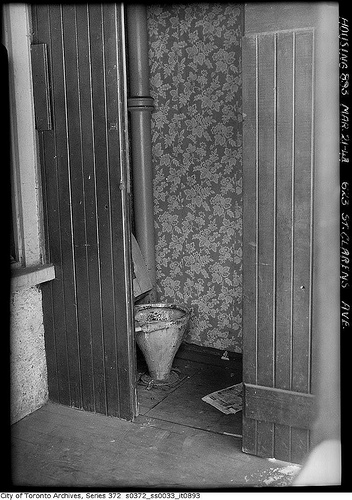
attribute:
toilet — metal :
[132, 303, 198, 388]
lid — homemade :
[133, 237, 154, 301]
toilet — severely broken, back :
[118, 234, 188, 382]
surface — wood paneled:
[245, 28, 323, 421]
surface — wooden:
[60, 414, 187, 482]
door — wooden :
[30, 1, 140, 421]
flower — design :
[179, 103, 217, 141]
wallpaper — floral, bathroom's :
[147, 5, 242, 352]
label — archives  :
[107, 489, 121, 499]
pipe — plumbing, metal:
[127, 34, 157, 254]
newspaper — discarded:
[201, 381, 243, 417]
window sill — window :
[11, 264, 62, 285]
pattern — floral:
[163, 117, 230, 291]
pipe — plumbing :
[124, 2, 158, 303]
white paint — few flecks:
[238, 455, 302, 483]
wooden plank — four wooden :
[240, 34, 257, 457]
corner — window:
[7, 229, 37, 266]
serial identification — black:
[0, 494, 201, 498]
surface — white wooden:
[14, 257, 55, 290]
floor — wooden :
[18, 401, 336, 481]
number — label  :
[108, 487, 208, 498]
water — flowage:
[136, 168, 157, 298]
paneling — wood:
[248, 26, 310, 456]